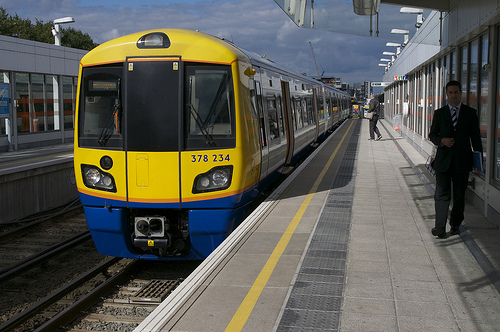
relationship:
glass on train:
[294, 92, 319, 129] [81, 25, 258, 242]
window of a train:
[183, 67, 234, 136] [71, 23, 359, 263]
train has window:
[60, 15, 361, 283] [74, 56, 239, 168]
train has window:
[60, 15, 361, 283] [78, 58, 126, 146]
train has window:
[60, 15, 361, 283] [180, 56, 238, 153]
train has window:
[60, 15, 361, 283] [263, 86, 285, 153]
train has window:
[60, 15, 361, 283] [288, 93, 308, 141]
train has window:
[60, 15, 361, 283] [308, 90, 325, 125]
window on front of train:
[183, 67, 234, 136] [78, 30, 375, 278]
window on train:
[183, 67, 234, 136] [60, 15, 361, 283]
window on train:
[183, 67, 234, 136] [71, 23, 359, 263]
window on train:
[253, 81, 268, 152] [71, 23, 359, 263]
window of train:
[253, 78, 269, 150] [60, 15, 361, 283]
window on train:
[267, 56, 367, 171] [60, 15, 361, 283]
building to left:
[3, 30, 88, 153] [4, 0, 99, 330]